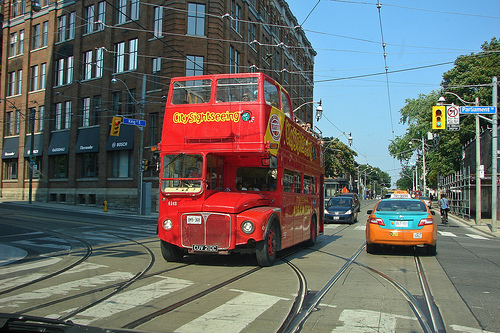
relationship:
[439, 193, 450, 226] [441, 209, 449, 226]
person on bike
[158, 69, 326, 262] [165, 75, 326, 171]
bus has an upper deck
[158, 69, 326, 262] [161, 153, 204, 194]
bus has a front window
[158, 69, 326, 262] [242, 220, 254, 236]
bus has headlights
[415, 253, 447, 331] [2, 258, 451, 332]
tracks on street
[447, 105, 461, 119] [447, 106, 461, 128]
an arrow on street sign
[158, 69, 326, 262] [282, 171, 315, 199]
bus has side windows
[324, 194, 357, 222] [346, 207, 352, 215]
car has headlights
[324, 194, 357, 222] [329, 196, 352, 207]
black cars front window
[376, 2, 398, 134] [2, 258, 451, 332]
wires are above street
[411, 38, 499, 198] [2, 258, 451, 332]
trees lining street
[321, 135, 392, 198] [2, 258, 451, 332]
trees lining street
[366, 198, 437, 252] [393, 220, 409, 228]
taxi has a license plate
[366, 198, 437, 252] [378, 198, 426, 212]
taxi has a back window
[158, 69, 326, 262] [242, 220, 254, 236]
bus has a headlight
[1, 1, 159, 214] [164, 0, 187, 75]
building made of bricks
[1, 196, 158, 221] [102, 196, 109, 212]
sidewalk has a fire hydrant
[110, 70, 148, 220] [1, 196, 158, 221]
streetlight on sidewalk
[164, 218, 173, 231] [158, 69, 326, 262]
headlight on bus